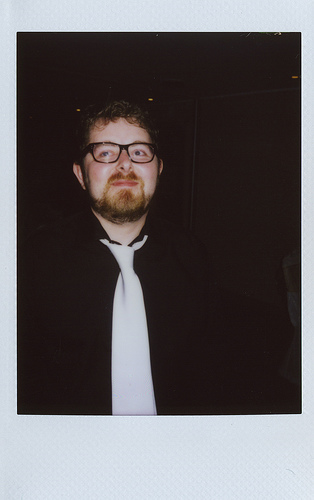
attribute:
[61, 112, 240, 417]
man — standing, looking, red, white, dressed, short, chubby, smiling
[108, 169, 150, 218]
beard — red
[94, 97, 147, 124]
hair — red, curly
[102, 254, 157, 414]
tie — white, large, silver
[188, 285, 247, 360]
shirt — black